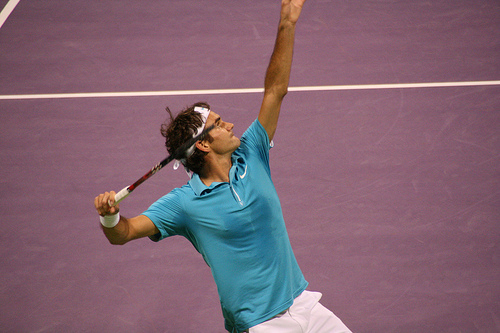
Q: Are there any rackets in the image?
A: Yes, there is a racket.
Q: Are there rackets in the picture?
A: Yes, there is a racket.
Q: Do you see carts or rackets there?
A: Yes, there is a racket.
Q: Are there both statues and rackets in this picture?
A: No, there is a racket but no statues.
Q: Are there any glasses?
A: No, there are no glasses.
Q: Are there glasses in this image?
A: No, there are no glasses.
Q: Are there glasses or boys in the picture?
A: No, there are no glasses or boys.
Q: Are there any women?
A: No, there are no women.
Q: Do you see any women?
A: No, there are no women.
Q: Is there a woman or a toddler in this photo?
A: No, there are no women or toddlers.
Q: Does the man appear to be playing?
A: Yes, the man is playing.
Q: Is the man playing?
A: Yes, the man is playing.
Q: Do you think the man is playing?
A: Yes, the man is playing.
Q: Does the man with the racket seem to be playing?
A: Yes, the man is playing.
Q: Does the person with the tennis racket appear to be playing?
A: Yes, the man is playing.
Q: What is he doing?
A: The man is playing.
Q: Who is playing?
A: The man is playing.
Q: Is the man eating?
A: No, the man is playing.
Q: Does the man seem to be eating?
A: No, the man is playing.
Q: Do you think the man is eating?
A: No, the man is playing.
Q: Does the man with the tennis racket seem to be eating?
A: No, the man is playing.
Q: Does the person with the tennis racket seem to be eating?
A: No, the man is playing.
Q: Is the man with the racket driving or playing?
A: The man is playing.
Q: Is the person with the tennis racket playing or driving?
A: The man is playing.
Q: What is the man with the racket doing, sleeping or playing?
A: The man is playing.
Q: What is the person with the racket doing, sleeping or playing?
A: The man is playing.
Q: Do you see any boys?
A: No, there are no boys.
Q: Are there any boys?
A: No, there are no boys.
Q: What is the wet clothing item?
A: The clothing item is a polo shirt.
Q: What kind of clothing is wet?
A: The clothing is a polo shirt.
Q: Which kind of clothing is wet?
A: The clothing is a polo shirt.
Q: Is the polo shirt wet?
A: Yes, the polo shirt is wet.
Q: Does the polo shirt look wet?
A: Yes, the polo shirt is wet.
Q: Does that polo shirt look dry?
A: No, the polo shirt is wet.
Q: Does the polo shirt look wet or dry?
A: The polo shirt is wet.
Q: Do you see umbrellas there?
A: No, there are no umbrellas.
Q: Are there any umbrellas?
A: No, there are no umbrellas.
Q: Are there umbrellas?
A: No, there are no umbrellas.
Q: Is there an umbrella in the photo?
A: No, there are no umbrellas.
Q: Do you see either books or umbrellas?
A: No, there are no umbrellas or books.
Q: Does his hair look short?
A: Yes, the hair is short.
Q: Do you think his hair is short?
A: Yes, the hair is short.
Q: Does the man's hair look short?
A: Yes, the hair is short.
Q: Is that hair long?
A: No, the hair is short.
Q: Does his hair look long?
A: No, the hair is short.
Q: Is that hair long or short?
A: The hair is short.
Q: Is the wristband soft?
A: Yes, the wristband is soft.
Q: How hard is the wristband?
A: The wristband is soft.